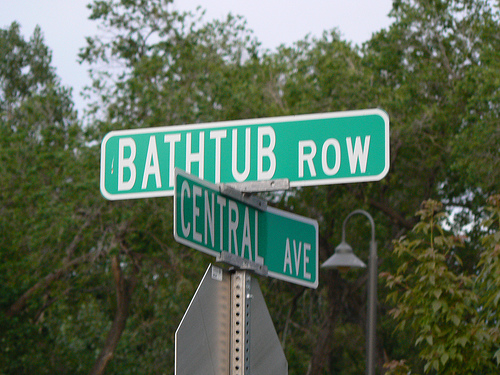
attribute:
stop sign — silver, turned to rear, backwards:
[174, 261, 289, 374]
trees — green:
[1, 0, 499, 374]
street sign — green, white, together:
[97, 108, 396, 293]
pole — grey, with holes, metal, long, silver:
[226, 267, 254, 375]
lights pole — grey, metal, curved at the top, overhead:
[320, 207, 380, 374]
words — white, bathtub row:
[117, 123, 371, 191]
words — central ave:
[179, 179, 312, 282]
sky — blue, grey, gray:
[1, 0, 499, 157]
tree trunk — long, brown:
[0, 201, 194, 374]